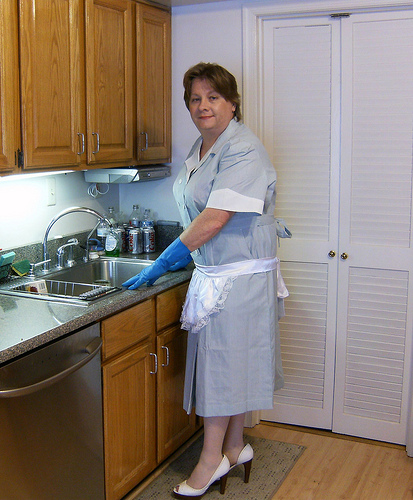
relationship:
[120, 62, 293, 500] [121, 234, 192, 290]
lady wearing rubber gloves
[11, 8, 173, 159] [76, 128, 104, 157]
cabinets with handles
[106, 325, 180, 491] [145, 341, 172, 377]
cabinets with handles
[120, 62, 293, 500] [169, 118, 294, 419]
lady in maid outfit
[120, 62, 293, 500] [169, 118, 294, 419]
lady wearing maid outfit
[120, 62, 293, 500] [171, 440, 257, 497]
lady wearing shoes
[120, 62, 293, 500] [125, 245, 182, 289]
lady wearing gloves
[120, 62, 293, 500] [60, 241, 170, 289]
lady at sink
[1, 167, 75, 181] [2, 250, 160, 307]
light over sink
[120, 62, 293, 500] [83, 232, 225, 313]
lady wearing gloves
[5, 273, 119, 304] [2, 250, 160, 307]
drain in sink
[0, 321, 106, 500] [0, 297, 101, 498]
cabinet in cabinet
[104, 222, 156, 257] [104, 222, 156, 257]
bottles behind bottles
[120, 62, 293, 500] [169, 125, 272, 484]
lady in maid outfit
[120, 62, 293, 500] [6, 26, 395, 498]
lady in kitchen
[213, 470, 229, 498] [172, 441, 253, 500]
heel on heels stiletto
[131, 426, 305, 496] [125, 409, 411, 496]
mat on floor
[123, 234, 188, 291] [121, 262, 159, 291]
glove on hands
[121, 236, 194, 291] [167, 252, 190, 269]
glove on hands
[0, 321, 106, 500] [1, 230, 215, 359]
cabinet under counter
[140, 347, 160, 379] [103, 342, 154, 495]
handle on cabinet door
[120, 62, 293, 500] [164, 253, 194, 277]
lady wearing glove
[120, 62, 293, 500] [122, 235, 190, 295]
lady wearing glove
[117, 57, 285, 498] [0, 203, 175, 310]
lady standing at sink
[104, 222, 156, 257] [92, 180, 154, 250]
bottles in corner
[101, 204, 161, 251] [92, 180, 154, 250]
bottles in corner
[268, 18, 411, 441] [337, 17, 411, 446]
closet has doors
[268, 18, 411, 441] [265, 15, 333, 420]
closet has doors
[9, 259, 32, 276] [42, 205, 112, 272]
sponge beside facuet